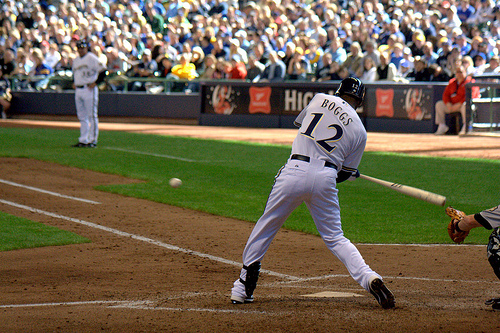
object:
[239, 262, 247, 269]
strap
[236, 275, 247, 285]
strap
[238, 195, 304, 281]
leg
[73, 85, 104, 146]
pants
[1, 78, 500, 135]
fence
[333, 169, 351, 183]
hand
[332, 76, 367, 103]
helmet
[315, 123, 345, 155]
number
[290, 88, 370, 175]
jersey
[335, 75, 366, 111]
head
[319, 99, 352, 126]
name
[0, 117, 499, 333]
ground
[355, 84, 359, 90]
number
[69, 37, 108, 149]
coach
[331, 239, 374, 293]
shin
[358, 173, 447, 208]
bat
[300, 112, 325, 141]
number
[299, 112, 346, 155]
12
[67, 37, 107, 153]
man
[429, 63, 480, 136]
man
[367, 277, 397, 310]
shoe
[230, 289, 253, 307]
shoe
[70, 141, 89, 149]
shoe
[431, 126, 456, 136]
shoe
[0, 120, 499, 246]
grass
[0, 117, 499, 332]
baseball field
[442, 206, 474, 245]
glove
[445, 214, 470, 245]
hand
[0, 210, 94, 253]
grass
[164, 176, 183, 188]
ball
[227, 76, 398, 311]
batter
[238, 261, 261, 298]
padding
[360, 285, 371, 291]
ankle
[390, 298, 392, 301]
stud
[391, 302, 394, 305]
stud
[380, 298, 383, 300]
stud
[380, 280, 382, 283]
stud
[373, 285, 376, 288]
stud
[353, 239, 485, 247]
line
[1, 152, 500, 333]
dirt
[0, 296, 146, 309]
line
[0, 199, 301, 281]
line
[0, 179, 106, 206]
line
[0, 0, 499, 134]
stands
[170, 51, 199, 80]
spectator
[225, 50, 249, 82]
spectator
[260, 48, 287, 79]
spectator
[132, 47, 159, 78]
spectator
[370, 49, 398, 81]
spectator